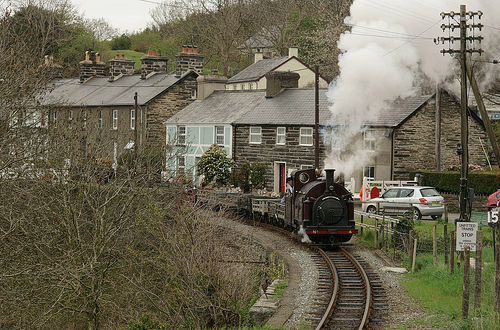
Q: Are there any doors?
A: Yes, there is a door.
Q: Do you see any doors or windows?
A: Yes, there is a door.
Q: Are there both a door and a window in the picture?
A: Yes, there are both a door and a window.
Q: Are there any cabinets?
A: No, there are no cabinets.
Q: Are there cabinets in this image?
A: No, there are no cabinets.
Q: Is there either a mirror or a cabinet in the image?
A: No, there are no cabinets or mirrors.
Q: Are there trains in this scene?
A: Yes, there is a train.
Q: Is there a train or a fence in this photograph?
A: Yes, there is a train.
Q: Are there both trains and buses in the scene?
A: No, there is a train but no buses.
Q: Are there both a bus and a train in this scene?
A: No, there is a train but no buses.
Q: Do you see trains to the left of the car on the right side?
A: Yes, there is a train to the left of the car.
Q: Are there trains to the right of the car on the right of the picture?
A: No, the train is to the left of the car.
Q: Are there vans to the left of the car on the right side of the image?
A: No, there is a train to the left of the car.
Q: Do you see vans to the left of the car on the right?
A: No, there is a train to the left of the car.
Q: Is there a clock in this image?
A: No, there are no clocks.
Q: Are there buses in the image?
A: No, there are no buses.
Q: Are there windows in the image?
A: Yes, there are windows.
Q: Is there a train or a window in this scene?
A: Yes, there are windows.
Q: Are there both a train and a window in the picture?
A: Yes, there are both a window and a train.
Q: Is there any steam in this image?
A: Yes, there is steam.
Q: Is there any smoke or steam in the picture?
A: Yes, there is steam.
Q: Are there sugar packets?
A: No, there are no sugar packets.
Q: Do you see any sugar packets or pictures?
A: No, there are no sugar packets or pictures.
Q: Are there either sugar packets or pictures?
A: No, there are no sugar packets or pictures.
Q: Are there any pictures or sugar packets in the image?
A: No, there are no sugar packets or pictures.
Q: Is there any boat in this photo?
A: No, there are no boats.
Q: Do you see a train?
A: Yes, there is a train.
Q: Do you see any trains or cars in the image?
A: Yes, there is a train.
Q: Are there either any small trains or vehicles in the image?
A: Yes, there is a small train.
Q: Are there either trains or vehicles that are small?
A: Yes, the train is small.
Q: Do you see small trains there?
A: Yes, there is a small train.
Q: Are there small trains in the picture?
A: Yes, there is a small train.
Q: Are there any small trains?
A: Yes, there is a small train.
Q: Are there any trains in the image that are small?
A: Yes, there is a train that is small.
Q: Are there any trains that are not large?
A: Yes, there is a small train.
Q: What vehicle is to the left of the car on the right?
A: The vehicle is a train.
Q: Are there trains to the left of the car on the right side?
A: Yes, there is a train to the left of the car.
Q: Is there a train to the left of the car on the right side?
A: Yes, there is a train to the left of the car.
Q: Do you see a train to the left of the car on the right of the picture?
A: Yes, there is a train to the left of the car.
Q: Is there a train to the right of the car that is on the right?
A: No, the train is to the left of the car.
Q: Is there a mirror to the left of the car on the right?
A: No, there is a train to the left of the car.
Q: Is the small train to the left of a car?
A: Yes, the train is to the left of a car.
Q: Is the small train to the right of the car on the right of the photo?
A: No, the train is to the left of the car.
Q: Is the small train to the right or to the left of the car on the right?
A: The train is to the left of the car.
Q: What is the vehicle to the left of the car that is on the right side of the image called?
A: The vehicle is a locomotive.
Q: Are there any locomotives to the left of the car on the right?
A: Yes, there is a locomotive to the left of the car.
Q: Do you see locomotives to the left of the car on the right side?
A: Yes, there is a locomotive to the left of the car.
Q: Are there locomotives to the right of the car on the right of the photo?
A: No, the locomotive is to the left of the car.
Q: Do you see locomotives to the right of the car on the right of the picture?
A: No, the locomotive is to the left of the car.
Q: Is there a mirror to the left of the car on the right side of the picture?
A: No, there is a locomotive to the left of the car.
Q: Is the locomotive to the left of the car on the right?
A: Yes, the locomotive is to the left of the car.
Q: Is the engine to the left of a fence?
A: No, the engine is to the left of the car.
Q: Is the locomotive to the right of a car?
A: No, the locomotive is to the left of a car.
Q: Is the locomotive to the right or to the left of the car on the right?
A: The locomotive is to the left of the car.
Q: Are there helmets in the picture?
A: No, there are no helmets.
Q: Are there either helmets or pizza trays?
A: No, there are no helmets or pizza trays.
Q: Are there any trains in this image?
A: Yes, there is a train.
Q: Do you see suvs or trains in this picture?
A: Yes, there is a train.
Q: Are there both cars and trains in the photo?
A: Yes, there are both a train and cars.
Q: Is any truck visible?
A: No, there are no trucks.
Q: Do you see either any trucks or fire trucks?
A: No, there are no trucks or fire trucks.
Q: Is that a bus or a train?
A: That is a train.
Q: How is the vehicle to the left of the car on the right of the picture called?
A: The vehicle is a train.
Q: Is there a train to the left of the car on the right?
A: Yes, there is a train to the left of the car.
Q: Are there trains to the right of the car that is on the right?
A: No, the train is to the left of the car.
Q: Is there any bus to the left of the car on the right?
A: No, there is a train to the left of the car.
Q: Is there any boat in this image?
A: No, there are no boats.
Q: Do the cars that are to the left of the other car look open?
A: Yes, the cars are open.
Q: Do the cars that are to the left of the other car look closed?
A: No, the cars are open.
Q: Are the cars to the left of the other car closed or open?
A: The cars are open.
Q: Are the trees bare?
A: Yes, the trees are bare.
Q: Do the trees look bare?
A: Yes, the trees are bare.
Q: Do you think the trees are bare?
A: Yes, the trees are bare.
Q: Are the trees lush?
A: No, the trees are bare.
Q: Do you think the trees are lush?
A: No, the trees are bare.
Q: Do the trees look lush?
A: No, the trees are bare.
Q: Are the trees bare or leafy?
A: The trees are bare.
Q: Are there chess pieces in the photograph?
A: No, there are no chess pieces.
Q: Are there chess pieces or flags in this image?
A: No, there are no chess pieces or flags.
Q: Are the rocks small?
A: Yes, the rocks are small.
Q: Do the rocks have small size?
A: Yes, the rocks are small.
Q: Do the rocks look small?
A: Yes, the rocks are small.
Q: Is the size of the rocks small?
A: Yes, the rocks are small.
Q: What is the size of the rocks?
A: The rocks are small.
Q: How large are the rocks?
A: The rocks are small.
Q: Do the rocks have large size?
A: No, the rocks are small.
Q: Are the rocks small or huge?
A: The rocks are small.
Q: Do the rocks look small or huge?
A: The rocks are small.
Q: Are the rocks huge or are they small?
A: The rocks are small.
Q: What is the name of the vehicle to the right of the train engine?
A: The vehicle is a car.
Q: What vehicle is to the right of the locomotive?
A: The vehicle is a car.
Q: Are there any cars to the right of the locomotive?
A: Yes, there is a car to the right of the locomotive.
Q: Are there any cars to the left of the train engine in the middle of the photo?
A: No, the car is to the right of the locomotive.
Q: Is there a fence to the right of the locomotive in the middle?
A: No, there is a car to the right of the locomotive.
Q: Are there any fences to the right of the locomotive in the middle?
A: No, there is a car to the right of the locomotive.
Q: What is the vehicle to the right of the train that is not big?
A: The vehicle is a car.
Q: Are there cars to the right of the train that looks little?
A: Yes, there is a car to the right of the train.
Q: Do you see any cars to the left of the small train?
A: No, the car is to the right of the train.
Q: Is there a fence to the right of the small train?
A: No, there is a car to the right of the train.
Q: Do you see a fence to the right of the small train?
A: No, there is a car to the right of the train.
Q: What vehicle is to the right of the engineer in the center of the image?
A: The vehicle is a car.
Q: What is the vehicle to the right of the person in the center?
A: The vehicle is a car.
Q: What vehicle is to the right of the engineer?
A: The vehicle is a car.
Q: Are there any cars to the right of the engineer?
A: Yes, there is a car to the right of the engineer.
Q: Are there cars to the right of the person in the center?
A: Yes, there is a car to the right of the engineer.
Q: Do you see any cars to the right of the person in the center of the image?
A: Yes, there is a car to the right of the engineer.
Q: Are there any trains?
A: Yes, there is a train.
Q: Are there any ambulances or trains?
A: Yes, there is a train.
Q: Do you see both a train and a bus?
A: No, there is a train but no buses.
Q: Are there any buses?
A: No, there are no buses.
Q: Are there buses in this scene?
A: No, there are no buses.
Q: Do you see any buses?
A: No, there are no buses.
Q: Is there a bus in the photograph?
A: No, there are no buses.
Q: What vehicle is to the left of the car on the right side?
A: The vehicle is a train.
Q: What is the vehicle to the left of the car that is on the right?
A: The vehicle is a train.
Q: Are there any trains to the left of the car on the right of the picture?
A: Yes, there is a train to the left of the car.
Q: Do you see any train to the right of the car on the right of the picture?
A: No, the train is to the left of the car.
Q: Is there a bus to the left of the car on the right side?
A: No, there is a train to the left of the car.